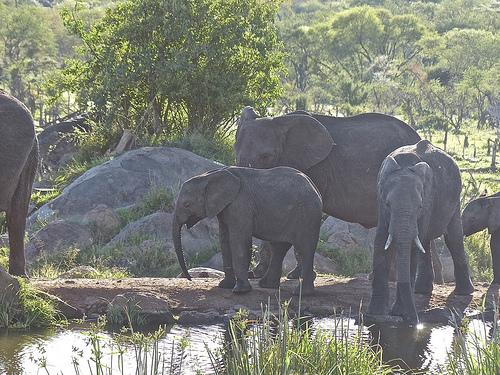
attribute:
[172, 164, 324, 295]
elephant — young, small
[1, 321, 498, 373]
water — greenish blue, small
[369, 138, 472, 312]
elephant — looking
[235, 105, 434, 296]
elephant — bigger, large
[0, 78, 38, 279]
elephant — part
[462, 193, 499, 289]
elephant — tiny, small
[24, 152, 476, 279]
boulders — big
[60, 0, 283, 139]
tree — large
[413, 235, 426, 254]
husk — white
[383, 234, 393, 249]
husk — white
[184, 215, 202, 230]
mouth — wet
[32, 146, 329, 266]
boulder — large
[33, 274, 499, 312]
path — small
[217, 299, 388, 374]
grass — tall